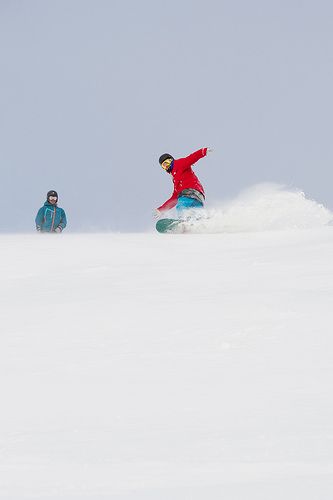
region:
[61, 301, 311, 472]
snow is white and blinding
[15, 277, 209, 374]
snow is white and blinding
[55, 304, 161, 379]
snow is white and blinding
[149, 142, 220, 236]
Person snowboarding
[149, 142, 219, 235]
Person in red jacket snowboarding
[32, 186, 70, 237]
Person in blue jacket watching snowboarder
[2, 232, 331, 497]
Snow covered ground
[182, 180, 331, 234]
Snow flying in air from snowboard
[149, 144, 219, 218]
Person wearing white gloves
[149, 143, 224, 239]
Person wearing black cap and yellow goggles riding a snowboard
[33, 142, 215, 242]
Two people on a snow covered hill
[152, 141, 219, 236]
Person wearing blue pants riding a snowboard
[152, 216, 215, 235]
Blue snowboard being ridden down a hill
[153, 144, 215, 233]
a person snowboarding on a slope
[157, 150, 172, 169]
the snowboarder is wearing a black helmet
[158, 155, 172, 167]
the boy is wearing yellow goggles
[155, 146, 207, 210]
a red ski jacket is on the boy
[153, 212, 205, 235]
the snowboard is green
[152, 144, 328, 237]
the snowboard is spraying snow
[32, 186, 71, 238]
a person is standing on the slope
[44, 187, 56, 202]
a black helmet and goggles are on the boy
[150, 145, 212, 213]
the snowboarder is wearing white ski gloves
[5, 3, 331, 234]
the sky is clear and blue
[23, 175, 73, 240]
young person wearing blue jacket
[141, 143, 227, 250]
young person riding snow board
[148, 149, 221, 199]
young person wearing red jacket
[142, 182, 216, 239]
young person wearing blue pants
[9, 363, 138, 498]
soft white snow on mountain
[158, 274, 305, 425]
soft white snow on mountain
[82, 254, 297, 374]
soft white snow on mountain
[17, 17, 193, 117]
blue cloudless sky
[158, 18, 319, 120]
blue cloudless sky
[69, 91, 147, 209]
blue cloudless sky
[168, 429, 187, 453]
snow covered hill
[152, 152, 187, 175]
person wearing a black hat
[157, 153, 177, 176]
person wearing yellow goggles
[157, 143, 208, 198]
person wearing a red jacket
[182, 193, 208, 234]
person wearing blue snow pants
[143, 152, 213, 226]
person riding a snow board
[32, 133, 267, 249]
two people snow boarding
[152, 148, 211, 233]
person wearing winter gear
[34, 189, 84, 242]
person in a black winter hat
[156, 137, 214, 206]
person wearing white gloves